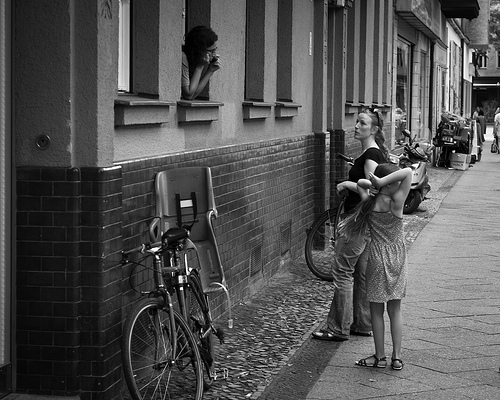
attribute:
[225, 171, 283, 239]
wall — brick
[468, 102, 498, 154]
people — few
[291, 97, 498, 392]
sidewalk — down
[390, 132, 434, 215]
scooter — background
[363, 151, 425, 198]
girl — little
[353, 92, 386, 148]
head — her , top